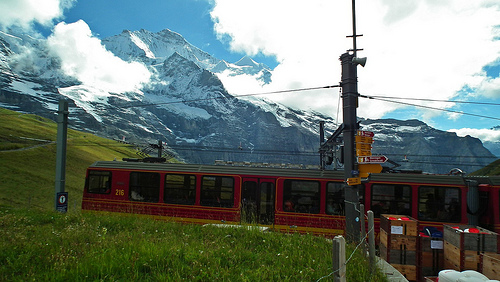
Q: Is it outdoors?
A: Yes, it is outdoors.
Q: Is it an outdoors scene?
A: Yes, it is outdoors.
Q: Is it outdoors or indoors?
A: It is outdoors.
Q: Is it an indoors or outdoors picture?
A: It is outdoors.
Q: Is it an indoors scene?
A: No, it is outdoors.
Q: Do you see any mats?
A: No, there are no mats.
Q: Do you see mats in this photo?
A: No, there are no mats.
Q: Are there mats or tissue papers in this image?
A: No, there are no mats or tissue papers.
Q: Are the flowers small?
A: Yes, the flowers are small.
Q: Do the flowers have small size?
A: Yes, the flowers are small.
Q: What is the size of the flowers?
A: The flowers are small.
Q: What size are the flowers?
A: The flowers are small.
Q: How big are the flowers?
A: The flowers are small.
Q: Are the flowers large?
A: No, the flowers are small.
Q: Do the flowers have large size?
A: No, the flowers are small.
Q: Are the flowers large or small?
A: The flowers are small.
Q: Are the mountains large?
A: Yes, the mountains are large.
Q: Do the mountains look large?
A: Yes, the mountains are large.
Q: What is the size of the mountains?
A: The mountains are large.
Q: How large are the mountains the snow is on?
A: The mountains are large.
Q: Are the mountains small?
A: No, the mountains are large.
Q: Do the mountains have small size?
A: No, the mountains are large.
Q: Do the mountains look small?
A: No, the mountains are large.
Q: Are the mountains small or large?
A: The mountains are large.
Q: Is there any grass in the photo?
A: Yes, there is grass.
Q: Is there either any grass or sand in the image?
A: Yes, there is grass.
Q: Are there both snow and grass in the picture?
A: Yes, there are both grass and snow.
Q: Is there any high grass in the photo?
A: Yes, there is high grass.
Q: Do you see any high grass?
A: Yes, there is high grass.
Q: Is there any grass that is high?
A: Yes, there is grass that is high.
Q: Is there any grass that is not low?
A: Yes, there is high grass.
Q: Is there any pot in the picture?
A: No, there are no pots.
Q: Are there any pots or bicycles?
A: No, there are no pots or bicycles.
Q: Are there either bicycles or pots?
A: No, there are no pots or bicycles.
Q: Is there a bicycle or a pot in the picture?
A: No, there are no pots or bicycles.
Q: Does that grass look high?
A: Yes, the grass is high.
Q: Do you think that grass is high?
A: Yes, the grass is high.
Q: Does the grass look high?
A: Yes, the grass is high.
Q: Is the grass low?
A: No, the grass is high.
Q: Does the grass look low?
A: No, the grass is high.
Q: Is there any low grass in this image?
A: No, there is grass but it is high.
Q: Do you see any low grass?
A: No, there is grass but it is high.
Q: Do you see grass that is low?
A: No, there is grass but it is high.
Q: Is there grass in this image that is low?
A: No, there is grass but it is high.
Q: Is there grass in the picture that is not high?
A: No, there is grass but it is high.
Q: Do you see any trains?
A: Yes, there is a train.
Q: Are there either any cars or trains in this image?
A: Yes, there is a train.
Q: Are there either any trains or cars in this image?
A: Yes, there is a train.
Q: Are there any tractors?
A: No, there are no tractors.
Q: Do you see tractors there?
A: No, there are no tractors.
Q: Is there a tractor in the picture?
A: No, there are no tractors.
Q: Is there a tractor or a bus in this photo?
A: No, there are no tractors or buses.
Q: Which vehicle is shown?
A: The vehicle is a train.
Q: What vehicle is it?
A: The vehicle is a train.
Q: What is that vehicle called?
A: This is a train.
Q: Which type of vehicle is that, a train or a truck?
A: This is a train.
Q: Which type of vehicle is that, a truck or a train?
A: This is a train.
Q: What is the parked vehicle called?
A: The vehicle is a train.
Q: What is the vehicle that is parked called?
A: The vehicle is a train.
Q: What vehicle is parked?
A: The vehicle is a train.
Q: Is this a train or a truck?
A: This is a train.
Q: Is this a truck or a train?
A: This is a train.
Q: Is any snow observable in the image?
A: Yes, there is snow.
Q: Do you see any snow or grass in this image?
A: Yes, there is snow.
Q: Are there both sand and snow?
A: No, there is snow but no sand.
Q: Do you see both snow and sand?
A: No, there is snow but no sand.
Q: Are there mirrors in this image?
A: No, there are no mirrors.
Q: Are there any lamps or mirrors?
A: No, there are no mirrors or lamps.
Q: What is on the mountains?
A: The snow is on the mountains.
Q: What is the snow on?
A: The snow is on the mountains.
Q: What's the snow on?
A: The snow is on the mountains.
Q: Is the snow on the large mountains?
A: Yes, the snow is on the mountains.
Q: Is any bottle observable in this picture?
A: No, there are no bottles.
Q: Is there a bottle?
A: No, there are no bottles.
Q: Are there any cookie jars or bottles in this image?
A: No, there are no bottles or cookie jars.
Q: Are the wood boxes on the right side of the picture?
A: Yes, the boxes are on the right of the image.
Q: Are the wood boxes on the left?
A: No, the boxes are on the right of the image.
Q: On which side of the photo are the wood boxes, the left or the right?
A: The boxes are on the right of the image.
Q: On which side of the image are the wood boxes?
A: The boxes are on the right of the image.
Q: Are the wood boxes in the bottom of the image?
A: Yes, the boxes are in the bottom of the image.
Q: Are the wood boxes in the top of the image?
A: No, the boxes are in the bottom of the image.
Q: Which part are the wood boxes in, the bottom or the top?
A: The boxes are in the bottom of the image.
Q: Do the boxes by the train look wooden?
A: Yes, the boxes are wooden.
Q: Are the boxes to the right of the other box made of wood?
A: Yes, the boxes are made of wood.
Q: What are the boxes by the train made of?
A: The boxes are made of wood.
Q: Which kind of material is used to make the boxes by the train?
A: The boxes are made of wood.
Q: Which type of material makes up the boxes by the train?
A: The boxes are made of wood.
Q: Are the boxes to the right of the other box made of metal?
A: No, the boxes are made of wood.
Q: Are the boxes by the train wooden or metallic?
A: The boxes are wooden.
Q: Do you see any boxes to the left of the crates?
A: Yes, there are boxes to the left of the crates.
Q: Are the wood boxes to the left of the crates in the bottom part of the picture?
A: Yes, the boxes are to the left of the crates.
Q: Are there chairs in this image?
A: No, there are no chairs.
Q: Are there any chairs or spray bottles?
A: No, there are no chairs or spray bottles.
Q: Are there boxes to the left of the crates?
A: Yes, there is a box to the left of the crates.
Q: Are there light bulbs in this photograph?
A: No, there are no light bulbs.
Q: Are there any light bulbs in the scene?
A: No, there are no light bulbs.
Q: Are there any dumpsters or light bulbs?
A: No, there are no light bulbs or dumpsters.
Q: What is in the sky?
A: The clouds are in the sky.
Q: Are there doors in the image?
A: Yes, there is a door.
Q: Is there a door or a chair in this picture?
A: Yes, there is a door.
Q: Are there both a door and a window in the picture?
A: Yes, there are both a door and a window.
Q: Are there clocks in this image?
A: No, there are no clocks.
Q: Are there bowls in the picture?
A: No, there are no bowls.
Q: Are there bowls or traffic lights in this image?
A: No, there are no bowls or traffic lights.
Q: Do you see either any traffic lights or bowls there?
A: No, there are no bowls or traffic lights.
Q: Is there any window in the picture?
A: Yes, there are windows.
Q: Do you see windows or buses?
A: Yes, there are windows.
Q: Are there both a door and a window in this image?
A: Yes, there are both a window and a door.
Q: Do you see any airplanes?
A: No, there are no airplanes.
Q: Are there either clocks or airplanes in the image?
A: No, there are no airplanes or clocks.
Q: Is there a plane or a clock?
A: No, there are no airplanes or clocks.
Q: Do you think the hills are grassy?
A: Yes, the hills are grassy.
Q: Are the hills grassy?
A: Yes, the hills are grassy.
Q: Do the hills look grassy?
A: Yes, the hills are grassy.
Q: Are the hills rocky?
A: No, the hills are grassy.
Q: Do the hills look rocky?
A: No, the hills are grassy.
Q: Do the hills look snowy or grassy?
A: The hills are grassy.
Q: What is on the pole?
A: The sign is on the pole.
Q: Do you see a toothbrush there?
A: No, there are no toothbrushes.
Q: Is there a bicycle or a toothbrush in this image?
A: No, there are no toothbrushes or bicycles.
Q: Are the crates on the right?
A: Yes, the crates are on the right of the image.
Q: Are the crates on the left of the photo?
A: No, the crates are on the right of the image.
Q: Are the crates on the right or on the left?
A: The crates are on the right of the image.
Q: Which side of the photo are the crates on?
A: The crates are on the right of the image.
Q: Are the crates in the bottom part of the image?
A: Yes, the crates are in the bottom of the image.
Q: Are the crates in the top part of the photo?
A: No, the crates are in the bottom of the image.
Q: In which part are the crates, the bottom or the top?
A: The crates are in the bottom of the image.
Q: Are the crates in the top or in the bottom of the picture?
A: The crates are in the bottom of the image.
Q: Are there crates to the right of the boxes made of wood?
A: Yes, there are crates to the right of the boxes.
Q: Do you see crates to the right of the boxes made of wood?
A: Yes, there are crates to the right of the boxes.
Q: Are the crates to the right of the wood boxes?
A: Yes, the crates are to the right of the boxes.